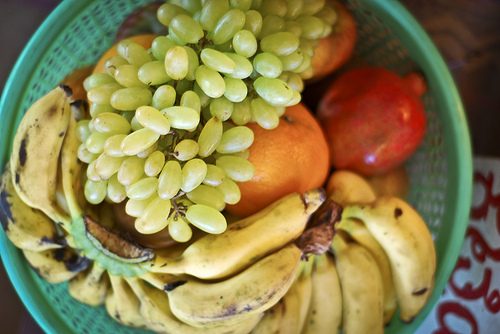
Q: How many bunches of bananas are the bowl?
A: 2.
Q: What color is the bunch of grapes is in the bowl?
A: Green.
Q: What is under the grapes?
A: An orange.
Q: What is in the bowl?
A: Different fruit.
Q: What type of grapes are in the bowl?
A: Thompson grapes.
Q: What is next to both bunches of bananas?
A: An orange.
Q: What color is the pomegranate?
A: Red.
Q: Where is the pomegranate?
A: Next to the orange.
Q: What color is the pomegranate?
A: Red.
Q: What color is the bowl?
A: Green.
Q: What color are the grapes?
A: Light green.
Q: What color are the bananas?
A: Yellow and black.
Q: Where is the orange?
A: Under the grapes.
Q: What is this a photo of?
A: Basket with variety of fruit.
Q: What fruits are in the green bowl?
A: Grapes, bananas. oranges, and a pomegranate.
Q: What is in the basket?
A: Fruit.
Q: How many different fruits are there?
A: Four.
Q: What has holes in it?
A: Basket.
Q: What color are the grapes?
A: Green.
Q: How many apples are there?
A: One.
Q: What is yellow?
A: Bananas.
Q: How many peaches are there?
A: None.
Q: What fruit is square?
A: None.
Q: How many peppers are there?
A: None.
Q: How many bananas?
A: Fourteen.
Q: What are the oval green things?
A: Green grapes.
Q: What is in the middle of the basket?
A: An orange.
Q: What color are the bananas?
A: Yellow.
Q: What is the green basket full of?
A: Fruit.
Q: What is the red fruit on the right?
A: Pomegranate.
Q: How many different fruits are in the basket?
A: Four.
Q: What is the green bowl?
A: A strainer.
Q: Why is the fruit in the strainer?
A: To wash the fruit.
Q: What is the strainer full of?
A: Fruit.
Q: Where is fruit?
A: In a basket.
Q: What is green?
A: Grapes.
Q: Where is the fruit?
A: Bowl.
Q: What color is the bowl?
A: Green.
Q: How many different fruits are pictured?
A: Four.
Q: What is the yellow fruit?
A: Bananas.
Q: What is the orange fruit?
A: Oranges.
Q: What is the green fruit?
A: Grapes.